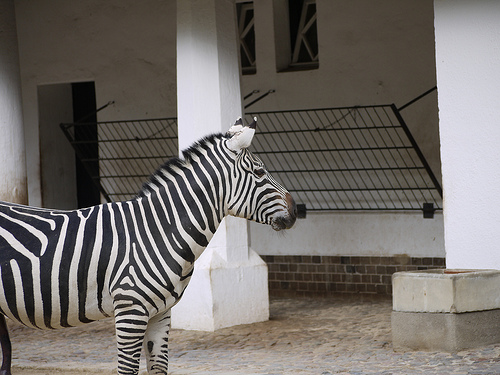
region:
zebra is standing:
[4, 122, 315, 341]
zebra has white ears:
[227, 127, 267, 154]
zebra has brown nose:
[268, 187, 309, 241]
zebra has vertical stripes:
[108, 117, 258, 285]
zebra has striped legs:
[85, 282, 218, 371]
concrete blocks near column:
[391, 245, 486, 362]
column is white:
[166, 15, 278, 335]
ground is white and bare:
[264, 285, 384, 373]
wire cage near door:
[237, 74, 433, 206]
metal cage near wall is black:
[224, 95, 424, 212]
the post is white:
[234, 280, 247, 304]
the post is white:
[217, 273, 232, 296]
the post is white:
[196, 284, 238, 331]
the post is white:
[224, 288, 265, 337]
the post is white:
[224, 289, 241, 311]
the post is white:
[219, 300, 249, 338]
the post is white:
[222, 303, 240, 318]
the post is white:
[214, 287, 231, 301]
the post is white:
[230, 293, 240, 312]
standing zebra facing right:
[28, 113, 318, 362]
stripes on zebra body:
[20, 226, 103, 309]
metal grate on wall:
[292, 96, 453, 225]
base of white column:
[205, 243, 279, 338]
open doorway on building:
[30, 68, 117, 205]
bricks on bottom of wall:
[292, 249, 398, 302]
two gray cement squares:
[376, 264, 484, 353]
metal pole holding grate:
[380, 85, 435, 125]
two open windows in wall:
[232, 0, 332, 71]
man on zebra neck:
[142, 127, 223, 205]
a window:
[281, 8, 363, 93]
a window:
[251, 5, 332, 68]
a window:
[257, 2, 318, 109]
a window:
[265, 1, 349, 136]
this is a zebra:
[5, 113, 300, 371]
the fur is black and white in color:
[55, 235, 107, 275]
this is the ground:
[235, 330, 347, 366]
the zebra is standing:
[0, 115, 295, 371]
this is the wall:
[318, 211, 378, 246]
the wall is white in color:
[325, 216, 384, 248]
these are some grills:
[318, 109, 430, 204]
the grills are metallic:
[321, 115, 391, 202]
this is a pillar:
[179, 80, 214, 117]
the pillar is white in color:
[213, 256, 255, 315]